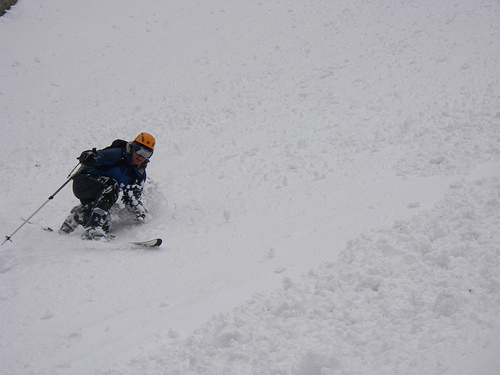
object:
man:
[60, 132, 157, 243]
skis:
[131, 238, 163, 248]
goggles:
[133, 142, 153, 160]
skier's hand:
[81, 150, 101, 165]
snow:
[0, 0, 500, 375]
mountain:
[310, 42, 491, 160]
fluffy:
[295, 55, 363, 101]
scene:
[87, 35, 464, 270]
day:
[59, 13, 434, 114]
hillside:
[219, 25, 392, 138]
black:
[73, 175, 96, 198]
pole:
[2, 164, 87, 243]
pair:
[129, 141, 153, 160]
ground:
[317, 79, 438, 144]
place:
[215, 50, 367, 165]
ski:
[257, 45, 381, 148]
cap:
[135, 132, 156, 150]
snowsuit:
[63, 132, 156, 236]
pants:
[87, 173, 120, 211]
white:
[107, 230, 167, 250]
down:
[146, 91, 442, 219]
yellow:
[135, 132, 156, 150]